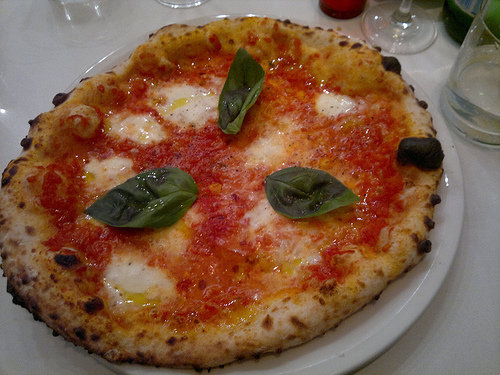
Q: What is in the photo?
A: A pizza.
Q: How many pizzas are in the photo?
A: One.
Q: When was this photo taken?
A: Meal time.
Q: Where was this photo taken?
A: At a restaurant.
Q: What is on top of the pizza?
A: Basil.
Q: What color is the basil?
A: Green.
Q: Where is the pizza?
A: On the plate.